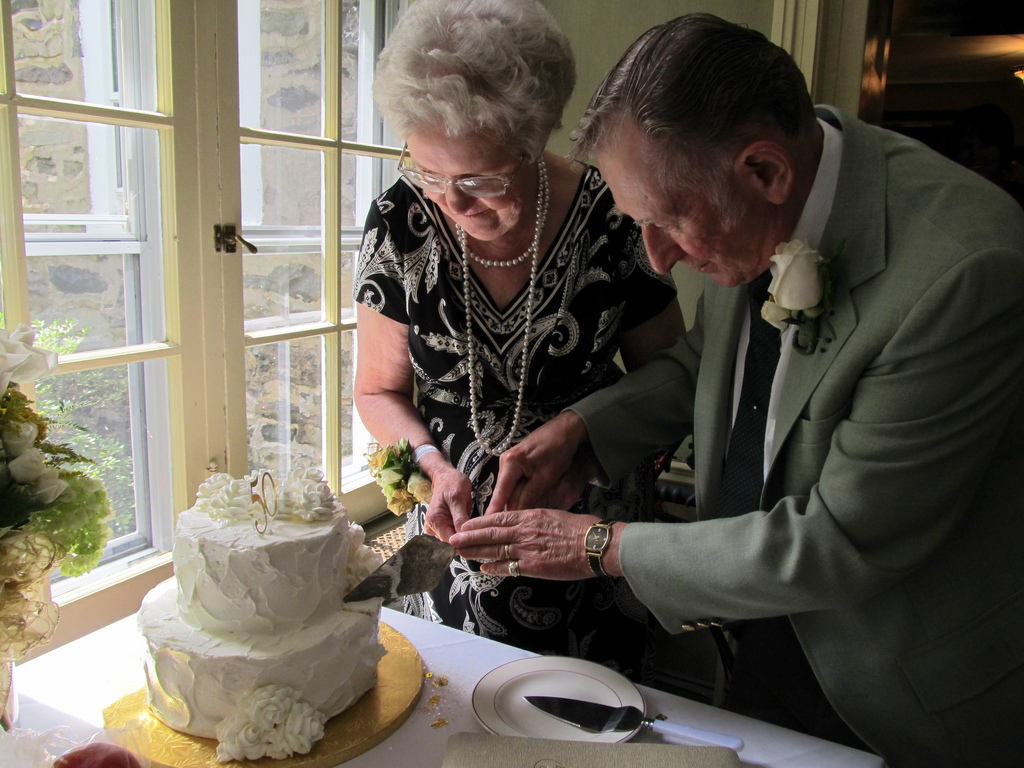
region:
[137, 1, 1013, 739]
elderly couple standing over cake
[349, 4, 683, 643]
woman with pearls around neck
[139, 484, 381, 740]
round cake with two tiers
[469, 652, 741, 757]
cake server on plate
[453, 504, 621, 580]
watch on man's wrist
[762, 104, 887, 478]
white rose on lapel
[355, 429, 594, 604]
hands on cake server handle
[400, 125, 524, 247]
glasses on woman's face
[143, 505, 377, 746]
white frosting on cake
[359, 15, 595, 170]
woman has grey hair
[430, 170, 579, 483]
woman has pearl necklace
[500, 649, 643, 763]
small and white plate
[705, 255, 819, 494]
man has black tie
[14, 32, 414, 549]
white frame on window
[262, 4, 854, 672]
an elderly couple cutting a cake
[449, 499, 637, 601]
a hand wearing a watch and a couple of rings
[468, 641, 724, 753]
a cake slicer on a small plate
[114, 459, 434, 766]
an anniversary cake with the number 50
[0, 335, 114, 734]
floral arrangement on a table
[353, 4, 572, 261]
a lady with white hair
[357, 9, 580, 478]
a lady wearing long pearl necklace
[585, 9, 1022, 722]
a man wearing a grey suit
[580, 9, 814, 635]
a man wearing a black tie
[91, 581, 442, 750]
a golden circular base for a cake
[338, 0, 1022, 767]
two people cutting a cake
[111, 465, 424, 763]
cake on top of table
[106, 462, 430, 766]
cake has white frosting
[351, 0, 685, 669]
woman has gray hair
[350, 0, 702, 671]
woman has pearl necklace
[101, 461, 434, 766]
cake has a number 50 on top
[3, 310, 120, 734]
flowers on top of table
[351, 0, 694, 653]
woman has black and white dress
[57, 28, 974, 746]
couple cutting an anniversary cake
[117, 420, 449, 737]
a 50th anniversary cake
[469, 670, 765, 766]
a silver utensil for serving cake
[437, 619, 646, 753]
a white plate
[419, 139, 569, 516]
a strand of pearls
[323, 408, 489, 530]
a flower corsage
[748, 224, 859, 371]
a white rose on a lapel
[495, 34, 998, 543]
man wearing a suit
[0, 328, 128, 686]
a bouquet of flowers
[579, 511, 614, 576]
a man's watch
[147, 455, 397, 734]
a small two layer cake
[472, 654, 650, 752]
a small white plate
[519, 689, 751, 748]
a white cake spatula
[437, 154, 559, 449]
a woman's long pearls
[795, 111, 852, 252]
a man's white shirt collar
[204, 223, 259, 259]
a dark window latch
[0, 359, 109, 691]
green and white flowers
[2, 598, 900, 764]
a white tablecloth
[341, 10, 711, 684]
woman cutting cake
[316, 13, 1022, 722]
man cutting the cake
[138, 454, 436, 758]
cake is white with flowers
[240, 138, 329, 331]
glass is clear and clean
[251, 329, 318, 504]
glass is clear and clean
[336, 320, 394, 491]
glass is clear and clean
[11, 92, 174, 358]
glass is clear and clean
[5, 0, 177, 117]
glass is clear and clean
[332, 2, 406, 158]
glass is clear and clean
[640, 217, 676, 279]
person has a nose